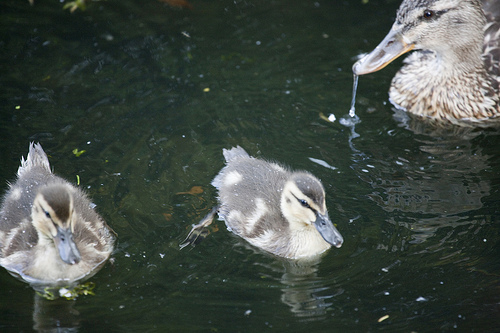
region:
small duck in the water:
[192, 130, 340, 272]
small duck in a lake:
[192, 137, 337, 288]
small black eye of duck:
[300, 198, 312, 209]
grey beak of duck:
[315, 216, 350, 251]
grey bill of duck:
[309, 212, 348, 253]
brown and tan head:
[32, 185, 71, 240]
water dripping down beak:
[335, 57, 377, 109]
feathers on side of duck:
[420, 69, 477, 120]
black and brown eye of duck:
[415, 6, 437, 28]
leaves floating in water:
[128, 169, 200, 231]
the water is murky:
[106, 45, 187, 143]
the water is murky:
[173, 97, 250, 122]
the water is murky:
[354, 201, 446, 317]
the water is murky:
[111, 145, 236, 307]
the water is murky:
[101, 72, 283, 174]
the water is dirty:
[149, 114, 351, 214]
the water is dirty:
[376, 158, 474, 314]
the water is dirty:
[108, 93, 213, 248]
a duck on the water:
[183, 133, 402, 307]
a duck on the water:
[12, 144, 164, 311]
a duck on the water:
[319, 19, 490, 177]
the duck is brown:
[161, 117, 413, 332]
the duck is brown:
[4, 131, 146, 311]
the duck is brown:
[331, 6, 497, 149]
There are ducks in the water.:
[209, 140, 348, 266]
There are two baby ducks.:
[2, 133, 344, 284]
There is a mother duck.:
[355, 2, 498, 133]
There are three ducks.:
[7, 4, 499, 297]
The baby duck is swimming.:
[183, 132, 353, 274]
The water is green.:
[126, 63, 202, 158]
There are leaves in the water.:
[68, 143, 85, 160]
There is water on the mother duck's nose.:
[336, 55, 366, 128]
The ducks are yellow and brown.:
[207, 140, 347, 266]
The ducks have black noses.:
[308, 203, 349, 256]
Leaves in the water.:
[78, 126, 214, 217]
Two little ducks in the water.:
[30, 158, 331, 264]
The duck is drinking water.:
[375, 17, 496, 124]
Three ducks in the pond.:
[24, 25, 491, 281]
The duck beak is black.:
[311, 216, 347, 251]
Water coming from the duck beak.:
[341, 48, 381, 99]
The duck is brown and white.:
[428, 42, 498, 111]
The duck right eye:
[288, 183, 313, 208]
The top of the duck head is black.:
[45, 175, 71, 230]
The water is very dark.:
[90, 18, 344, 112]